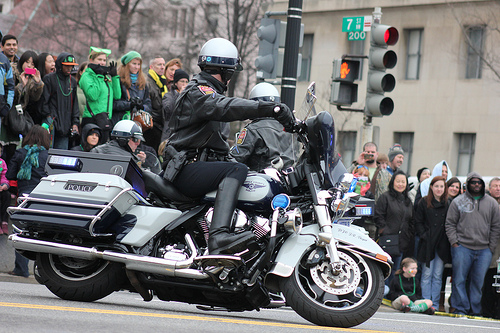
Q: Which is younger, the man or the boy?
A: The boy is younger than the man.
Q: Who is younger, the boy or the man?
A: The boy is younger than the man.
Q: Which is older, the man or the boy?
A: The man is older than the boy.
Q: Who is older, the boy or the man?
A: The man is older than the boy.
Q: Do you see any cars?
A: No, there are no cars.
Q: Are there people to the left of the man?
A: Yes, there are people to the left of the man.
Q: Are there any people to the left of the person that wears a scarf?
A: Yes, there are people to the left of the man.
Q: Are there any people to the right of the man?
A: No, the people are to the left of the man.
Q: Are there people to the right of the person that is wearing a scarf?
A: No, the people are to the left of the man.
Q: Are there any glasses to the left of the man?
A: No, there are people to the left of the man.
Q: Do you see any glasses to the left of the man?
A: No, there are people to the left of the man.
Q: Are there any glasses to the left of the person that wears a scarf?
A: No, there are people to the left of the man.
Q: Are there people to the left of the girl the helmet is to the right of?
A: Yes, there are people to the left of the girl.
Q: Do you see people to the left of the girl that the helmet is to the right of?
A: Yes, there are people to the left of the girl.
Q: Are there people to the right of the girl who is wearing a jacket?
A: No, the people are to the left of the girl.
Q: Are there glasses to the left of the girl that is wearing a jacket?
A: No, there are people to the left of the girl.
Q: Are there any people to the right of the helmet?
A: No, the people are to the left of the helmet.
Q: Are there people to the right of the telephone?
A: Yes, there are people to the right of the telephone.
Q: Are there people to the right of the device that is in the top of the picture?
A: Yes, there are people to the right of the telephone.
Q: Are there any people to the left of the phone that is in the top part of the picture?
A: No, the people are to the right of the phone.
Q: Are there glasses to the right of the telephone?
A: No, there are people to the right of the telephone.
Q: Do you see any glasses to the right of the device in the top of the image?
A: No, there are people to the right of the telephone.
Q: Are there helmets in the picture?
A: Yes, there is a helmet.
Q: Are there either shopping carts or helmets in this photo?
A: Yes, there is a helmet.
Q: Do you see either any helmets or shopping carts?
A: Yes, there is a helmet.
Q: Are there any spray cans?
A: No, there are no spray cans.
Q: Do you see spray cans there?
A: No, there are no spray cans.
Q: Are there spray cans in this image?
A: No, there are no spray cans.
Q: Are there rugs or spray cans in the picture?
A: No, there are no spray cans or rugs.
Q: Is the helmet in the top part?
A: Yes, the helmet is in the top of the image.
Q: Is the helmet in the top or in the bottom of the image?
A: The helmet is in the top of the image.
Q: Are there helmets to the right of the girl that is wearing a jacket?
A: Yes, there is a helmet to the right of the girl.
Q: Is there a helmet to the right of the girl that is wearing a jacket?
A: Yes, there is a helmet to the right of the girl.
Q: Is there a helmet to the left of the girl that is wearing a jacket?
A: No, the helmet is to the right of the girl.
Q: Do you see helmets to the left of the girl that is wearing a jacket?
A: No, the helmet is to the right of the girl.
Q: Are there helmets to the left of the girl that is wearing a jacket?
A: No, the helmet is to the right of the girl.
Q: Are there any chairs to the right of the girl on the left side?
A: No, there is a helmet to the right of the girl.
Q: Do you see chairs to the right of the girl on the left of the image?
A: No, there is a helmet to the right of the girl.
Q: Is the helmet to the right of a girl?
A: Yes, the helmet is to the right of a girl.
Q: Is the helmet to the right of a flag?
A: No, the helmet is to the right of a girl.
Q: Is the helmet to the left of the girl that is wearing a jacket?
A: No, the helmet is to the right of the girl.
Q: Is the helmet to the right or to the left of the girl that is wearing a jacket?
A: The helmet is to the right of the girl.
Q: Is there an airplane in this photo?
A: No, there are no airplanes.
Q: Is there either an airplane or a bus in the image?
A: No, there are no airplanes or buses.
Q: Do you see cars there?
A: No, there are no cars.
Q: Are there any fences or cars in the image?
A: No, there are no cars or fences.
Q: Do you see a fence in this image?
A: No, there are no fences.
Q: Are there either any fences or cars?
A: No, there are no fences or cars.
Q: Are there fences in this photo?
A: No, there are no fences.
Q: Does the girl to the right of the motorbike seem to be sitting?
A: Yes, the girl is sitting.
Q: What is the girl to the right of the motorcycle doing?
A: The girl is sitting.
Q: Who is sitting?
A: The girl is sitting.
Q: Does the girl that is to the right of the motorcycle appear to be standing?
A: No, the girl is sitting.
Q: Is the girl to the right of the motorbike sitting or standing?
A: The girl is sitting.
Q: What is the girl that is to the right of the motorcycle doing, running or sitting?
A: The girl is sitting.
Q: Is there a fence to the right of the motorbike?
A: No, there is a girl to the right of the motorbike.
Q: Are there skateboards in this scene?
A: No, there are no skateboards.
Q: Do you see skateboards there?
A: No, there are no skateboards.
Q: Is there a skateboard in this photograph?
A: No, there are no skateboards.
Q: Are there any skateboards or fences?
A: No, there are no skateboards or fences.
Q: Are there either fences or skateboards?
A: No, there are no skateboards or fences.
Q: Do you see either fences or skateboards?
A: No, there are no skateboards or fences.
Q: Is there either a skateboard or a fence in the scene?
A: No, there are no skateboards or fences.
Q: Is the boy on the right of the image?
A: Yes, the boy is on the right of the image.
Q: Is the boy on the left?
A: No, the boy is on the right of the image.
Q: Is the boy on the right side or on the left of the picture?
A: The boy is on the right of the image.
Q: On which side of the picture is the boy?
A: The boy is on the right of the image.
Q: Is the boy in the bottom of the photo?
A: Yes, the boy is in the bottom of the image.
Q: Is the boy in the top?
A: No, the boy is in the bottom of the image.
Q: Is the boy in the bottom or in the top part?
A: The boy is in the bottom of the image.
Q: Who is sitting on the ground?
A: The boy is sitting on the ground.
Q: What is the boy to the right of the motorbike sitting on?
A: The boy is sitting on the ground.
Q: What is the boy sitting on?
A: The boy is sitting on the ground.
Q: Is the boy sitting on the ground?
A: Yes, the boy is sitting on the ground.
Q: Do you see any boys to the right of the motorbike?
A: Yes, there is a boy to the right of the motorbike.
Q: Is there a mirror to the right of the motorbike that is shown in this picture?
A: No, there is a boy to the right of the motorbike.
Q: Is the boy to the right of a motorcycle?
A: Yes, the boy is to the right of a motorcycle.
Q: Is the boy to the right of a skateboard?
A: No, the boy is to the right of a motorcycle.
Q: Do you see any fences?
A: No, there are no fences.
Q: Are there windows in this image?
A: Yes, there are windows.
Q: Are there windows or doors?
A: Yes, there are windows.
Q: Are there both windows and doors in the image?
A: No, there are windows but no doors.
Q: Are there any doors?
A: No, there are no doors.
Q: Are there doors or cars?
A: No, there are no doors or cars.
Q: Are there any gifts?
A: No, there are no gifts.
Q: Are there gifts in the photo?
A: No, there are no gifts.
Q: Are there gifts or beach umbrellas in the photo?
A: No, there are no gifts or beach umbrellas.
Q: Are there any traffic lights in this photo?
A: Yes, there is a traffic light.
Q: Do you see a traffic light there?
A: Yes, there is a traffic light.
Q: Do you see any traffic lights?
A: Yes, there is a traffic light.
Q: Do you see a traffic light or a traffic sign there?
A: Yes, there is a traffic light.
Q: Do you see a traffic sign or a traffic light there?
A: Yes, there is a traffic light.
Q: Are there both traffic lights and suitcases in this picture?
A: No, there is a traffic light but no suitcases.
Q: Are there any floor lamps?
A: No, there are no floor lamps.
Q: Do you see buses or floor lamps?
A: No, there are no floor lamps or buses.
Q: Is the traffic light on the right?
A: Yes, the traffic light is on the right of the image.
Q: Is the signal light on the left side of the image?
A: No, the signal light is on the right of the image.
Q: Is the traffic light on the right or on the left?
A: The traffic light is on the right of the image.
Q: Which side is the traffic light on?
A: The traffic light is on the right of the image.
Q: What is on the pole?
A: The traffic light is on the pole.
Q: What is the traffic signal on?
A: The traffic signal is on the pole.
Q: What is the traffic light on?
A: The traffic signal is on the pole.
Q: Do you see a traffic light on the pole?
A: Yes, there is a traffic light on the pole.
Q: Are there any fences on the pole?
A: No, there is a traffic light on the pole.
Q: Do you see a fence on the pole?
A: No, there is a traffic light on the pole.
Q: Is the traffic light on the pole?
A: Yes, the traffic light is on the pole.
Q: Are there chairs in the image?
A: No, there are no chairs.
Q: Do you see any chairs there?
A: No, there are no chairs.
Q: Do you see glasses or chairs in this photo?
A: No, there are no chairs or glasses.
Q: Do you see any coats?
A: Yes, there is a coat.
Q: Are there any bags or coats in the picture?
A: Yes, there is a coat.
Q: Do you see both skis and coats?
A: No, there is a coat but no skis.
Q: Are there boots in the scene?
A: Yes, there are boots.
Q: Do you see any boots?
A: Yes, there are boots.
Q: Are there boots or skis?
A: Yes, there are boots.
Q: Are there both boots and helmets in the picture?
A: Yes, there are both boots and a helmet.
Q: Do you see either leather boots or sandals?
A: Yes, there are leather boots.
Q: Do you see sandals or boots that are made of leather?
A: Yes, the boots are made of leather.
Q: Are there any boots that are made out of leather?
A: Yes, there are boots that are made of leather.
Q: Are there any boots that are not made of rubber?
A: Yes, there are boots that are made of leather.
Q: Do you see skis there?
A: No, there are no skis.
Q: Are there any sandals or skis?
A: No, there are no skis or sandals.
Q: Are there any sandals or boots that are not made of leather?
A: No, there are boots but they are made of leather.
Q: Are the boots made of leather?
A: Yes, the boots are made of leather.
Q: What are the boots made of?
A: The boots are made of leather.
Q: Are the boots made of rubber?
A: No, the boots are made of leather.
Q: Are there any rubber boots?
A: No, there are boots but they are made of leather.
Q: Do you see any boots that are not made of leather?
A: No, there are boots but they are made of leather.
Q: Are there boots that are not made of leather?
A: No, there are boots but they are made of leather.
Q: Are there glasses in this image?
A: No, there are no glasses.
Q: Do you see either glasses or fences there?
A: No, there are no glasses or fences.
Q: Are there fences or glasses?
A: No, there are no glasses or fences.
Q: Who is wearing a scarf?
A: The man is wearing a scarf.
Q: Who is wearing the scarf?
A: The man is wearing a scarf.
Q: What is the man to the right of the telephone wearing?
A: The man is wearing a scarf.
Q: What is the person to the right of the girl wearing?
A: The man is wearing a scarf.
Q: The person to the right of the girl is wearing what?
A: The man is wearing a scarf.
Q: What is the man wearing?
A: The man is wearing a scarf.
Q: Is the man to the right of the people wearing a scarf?
A: Yes, the man is wearing a scarf.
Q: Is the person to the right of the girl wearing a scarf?
A: Yes, the man is wearing a scarf.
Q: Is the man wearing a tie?
A: No, the man is wearing a scarf.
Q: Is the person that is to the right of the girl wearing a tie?
A: No, the man is wearing a scarf.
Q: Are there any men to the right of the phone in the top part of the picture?
A: Yes, there is a man to the right of the telephone.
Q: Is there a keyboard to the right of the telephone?
A: No, there is a man to the right of the telephone.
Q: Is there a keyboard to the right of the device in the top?
A: No, there is a man to the right of the telephone.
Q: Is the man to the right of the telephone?
A: Yes, the man is to the right of the telephone.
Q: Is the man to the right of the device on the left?
A: Yes, the man is to the right of the telephone.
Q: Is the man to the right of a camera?
A: No, the man is to the right of the telephone.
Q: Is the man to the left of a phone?
A: No, the man is to the right of a phone.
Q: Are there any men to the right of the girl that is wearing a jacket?
A: Yes, there is a man to the right of the girl.